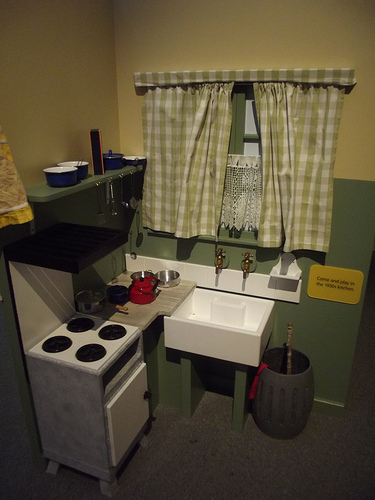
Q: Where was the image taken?
A: It was taken at the kitchen.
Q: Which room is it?
A: It is a kitchen.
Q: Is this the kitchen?
A: Yes, it is the kitchen.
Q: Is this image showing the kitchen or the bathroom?
A: It is showing the kitchen.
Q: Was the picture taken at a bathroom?
A: No, the picture was taken in a kitchen.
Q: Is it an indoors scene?
A: Yes, it is indoors.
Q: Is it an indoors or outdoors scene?
A: It is indoors.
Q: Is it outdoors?
A: No, it is indoors.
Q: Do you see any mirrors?
A: No, there are no mirrors.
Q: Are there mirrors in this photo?
A: No, there are no mirrors.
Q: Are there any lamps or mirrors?
A: No, there are no mirrors or lamps.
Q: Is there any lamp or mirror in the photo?
A: No, there are no mirrors or lamps.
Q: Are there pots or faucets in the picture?
A: Yes, there is a pot.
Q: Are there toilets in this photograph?
A: No, there are no toilets.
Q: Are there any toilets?
A: No, there are no toilets.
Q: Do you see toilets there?
A: No, there are no toilets.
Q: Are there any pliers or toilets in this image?
A: No, there are no toilets or pliers.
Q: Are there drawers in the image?
A: No, there are no drawers.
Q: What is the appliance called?
A: The appliance is a stove.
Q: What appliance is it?
A: The appliance is a stove.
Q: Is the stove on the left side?
A: Yes, the stove is on the left of the image.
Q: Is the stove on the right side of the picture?
A: No, the stove is on the left of the image.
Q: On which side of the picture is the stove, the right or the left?
A: The stove is on the left of the image.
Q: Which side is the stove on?
A: The stove is on the left of the image.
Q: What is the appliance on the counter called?
A: The appliance is a stove.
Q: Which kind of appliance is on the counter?
A: The appliance is a stove.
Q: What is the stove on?
A: The stove is on the counter.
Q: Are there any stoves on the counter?
A: Yes, there is a stove on the counter.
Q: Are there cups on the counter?
A: No, there is a stove on the counter.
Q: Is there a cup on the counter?
A: No, there is a stove on the counter.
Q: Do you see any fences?
A: No, there are no fences.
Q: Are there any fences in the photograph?
A: No, there are no fences.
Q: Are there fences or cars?
A: No, there are no fences or cars.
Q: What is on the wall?
A: The sign is on the wall.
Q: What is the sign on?
A: The sign is on the wall.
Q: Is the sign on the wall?
A: Yes, the sign is on the wall.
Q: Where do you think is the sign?
A: The sign is in the kitchen.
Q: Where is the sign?
A: The sign is in the kitchen.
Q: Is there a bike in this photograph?
A: No, there are no bikes.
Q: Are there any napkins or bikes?
A: No, there are no bikes or napkins.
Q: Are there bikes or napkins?
A: No, there are no bikes or napkins.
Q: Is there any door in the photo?
A: Yes, there is a door.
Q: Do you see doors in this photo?
A: Yes, there is a door.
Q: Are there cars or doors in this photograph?
A: Yes, there is a door.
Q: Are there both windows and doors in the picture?
A: Yes, there are both a door and windows.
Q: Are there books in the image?
A: No, there are no books.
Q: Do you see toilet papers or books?
A: No, there are no books or toilet papers.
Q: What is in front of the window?
A: The sink is in front of the window.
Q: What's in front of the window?
A: The sink is in front of the window.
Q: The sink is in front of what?
A: The sink is in front of the window.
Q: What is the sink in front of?
A: The sink is in front of the window.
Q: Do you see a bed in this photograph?
A: No, there are no beds.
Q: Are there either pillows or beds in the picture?
A: No, there are no beds or pillows.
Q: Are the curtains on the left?
A: No, the curtains are on the right of the image.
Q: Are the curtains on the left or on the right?
A: The curtains are on the right of the image.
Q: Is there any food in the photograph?
A: No, there is no food.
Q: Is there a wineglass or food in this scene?
A: No, there are no food or wine glasses.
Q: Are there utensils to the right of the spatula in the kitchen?
A: Yes, there is a utensil to the right of the spatula.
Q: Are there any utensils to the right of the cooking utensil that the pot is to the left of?
A: Yes, there is a utensil to the right of the spatula.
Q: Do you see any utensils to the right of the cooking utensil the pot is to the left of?
A: Yes, there is a utensil to the right of the spatula.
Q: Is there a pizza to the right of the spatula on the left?
A: No, there is a utensil to the right of the spatula.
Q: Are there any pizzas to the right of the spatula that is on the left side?
A: No, there is a utensil to the right of the spatula.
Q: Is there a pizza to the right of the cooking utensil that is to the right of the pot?
A: No, there is a utensil to the right of the spatula.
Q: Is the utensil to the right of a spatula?
A: Yes, the utensil is to the right of a spatula.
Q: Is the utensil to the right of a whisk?
A: No, the utensil is to the right of a spatula.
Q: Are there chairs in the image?
A: No, there are no chairs.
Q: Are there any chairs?
A: No, there are no chairs.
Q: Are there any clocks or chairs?
A: No, there are no chairs or clocks.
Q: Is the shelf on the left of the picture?
A: Yes, the shelf is on the left of the image.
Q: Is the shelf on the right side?
A: No, the shelf is on the left of the image.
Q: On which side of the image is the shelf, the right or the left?
A: The shelf is on the left of the image.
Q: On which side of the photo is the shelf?
A: The shelf is on the left of the image.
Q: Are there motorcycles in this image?
A: No, there are no motorcycles.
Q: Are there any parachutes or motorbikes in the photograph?
A: No, there are no motorbikes or parachutes.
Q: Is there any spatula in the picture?
A: Yes, there is a spatula.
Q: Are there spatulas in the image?
A: Yes, there is a spatula.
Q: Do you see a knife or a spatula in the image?
A: Yes, there is a spatula.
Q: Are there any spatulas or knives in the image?
A: Yes, there is a spatula.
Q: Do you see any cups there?
A: No, there are no cups.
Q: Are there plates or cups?
A: No, there are no cups or plates.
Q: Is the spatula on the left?
A: Yes, the spatula is on the left of the image.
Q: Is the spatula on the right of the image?
A: No, the spatula is on the left of the image.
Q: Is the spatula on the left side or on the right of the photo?
A: The spatula is on the left of the image.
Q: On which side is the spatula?
A: The spatula is on the left of the image.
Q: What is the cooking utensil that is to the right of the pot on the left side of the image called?
A: The cooking utensil is a spatula.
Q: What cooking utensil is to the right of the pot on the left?
A: The cooking utensil is a spatula.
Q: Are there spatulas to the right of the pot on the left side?
A: Yes, there is a spatula to the right of the pot.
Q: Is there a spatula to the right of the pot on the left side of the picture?
A: Yes, there is a spatula to the right of the pot.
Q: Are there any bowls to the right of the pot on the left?
A: No, there is a spatula to the right of the pot.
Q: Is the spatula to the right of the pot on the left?
A: Yes, the spatula is to the right of the pot.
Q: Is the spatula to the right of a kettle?
A: No, the spatula is to the right of the pot.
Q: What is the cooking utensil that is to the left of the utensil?
A: The cooking utensil is a spatula.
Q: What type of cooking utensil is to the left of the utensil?
A: The cooking utensil is a spatula.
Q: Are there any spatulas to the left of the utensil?
A: Yes, there is a spatula to the left of the utensil.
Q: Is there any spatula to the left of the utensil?
A: Yes, there is a spatula to the left of the utensil.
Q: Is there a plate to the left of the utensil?
A: No, there is a spatula to the left of the utensil.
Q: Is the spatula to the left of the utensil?
A: Yes, the spatula is to the left of the utensil.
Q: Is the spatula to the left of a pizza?
A: No, the spatula is to the left of the utensil.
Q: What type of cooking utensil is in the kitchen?
A: The cooking utensil is a spatula.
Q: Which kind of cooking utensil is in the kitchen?
A: The cooking utensil is a spatula.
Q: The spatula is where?
A: The spatula is in the kitchen.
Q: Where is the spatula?
A: The spatula is in the kitchen.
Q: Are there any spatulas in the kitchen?
A: Yes, there is a spatula in the kitchen.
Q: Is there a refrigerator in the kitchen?
A: No, there is a spatula in the kitchen.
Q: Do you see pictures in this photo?
A: No, there are no pictures.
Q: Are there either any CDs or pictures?
A: No, there are no pictures or cds.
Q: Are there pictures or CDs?
A: No, there are no pictures or cds.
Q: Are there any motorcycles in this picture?
A: No, there are no motorcycles.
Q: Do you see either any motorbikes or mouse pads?
A: No, there are no motorbikes or mouse pads.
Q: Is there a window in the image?
A: Yes, there is a window.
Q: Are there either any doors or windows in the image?
A: Yes, there is a window.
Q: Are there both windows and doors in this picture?
A: Yes, there are both a window and a door.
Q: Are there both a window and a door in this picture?
A: Yes, there are both a window and a door.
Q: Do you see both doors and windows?
A: Yes, there are both a window and a door.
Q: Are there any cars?
A: No, there are no cars.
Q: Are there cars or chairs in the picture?
A: No, there are no cars or chairs.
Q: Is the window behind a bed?
A: No, the window is behind the sink.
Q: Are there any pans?
A: Yes, there is a pan.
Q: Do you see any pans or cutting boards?
A: Yes, there is a pan.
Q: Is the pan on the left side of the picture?
A: Yes, the pan is on the left of the image.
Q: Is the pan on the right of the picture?
A: No, the pan is on the left of the image.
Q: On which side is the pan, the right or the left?
A: The pan is on the left of the image.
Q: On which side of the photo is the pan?
A: The pan is on the left of the image.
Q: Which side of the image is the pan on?
A: The pan is on the left of the image.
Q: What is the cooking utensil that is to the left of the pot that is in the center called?
A: The cooking utensil is a pan.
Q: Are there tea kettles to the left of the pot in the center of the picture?
A: No, there is a pan to the left of the pot.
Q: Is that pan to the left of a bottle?
A: No, the pan is to the left of the pot.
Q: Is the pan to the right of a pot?
A: No, the pan is to the left of a pot.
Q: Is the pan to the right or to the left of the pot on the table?
A: The pan is to the left of the pot.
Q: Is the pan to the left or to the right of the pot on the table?
A: The pan is to the left of the pot.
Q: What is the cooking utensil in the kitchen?
A: The cooking utensil is a pan.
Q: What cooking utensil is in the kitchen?
A: The cooking utensil is a pan.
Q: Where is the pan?
A: The pan is in the kitchen.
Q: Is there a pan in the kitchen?
A: Yes, there is a pan in the kitchen.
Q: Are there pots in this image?
A: Yes, there is a pot.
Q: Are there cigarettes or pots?
A: Yes, there is a pot.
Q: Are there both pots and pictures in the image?
A: No, there is a pot but no pictures.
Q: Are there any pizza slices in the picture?
A: No, there are no pizza slices.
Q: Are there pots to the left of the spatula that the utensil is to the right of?
A: Yes, there is a pot to the left of the spatula.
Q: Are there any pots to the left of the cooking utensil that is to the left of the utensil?
A: Yes, there is a pot to the left of the spatula.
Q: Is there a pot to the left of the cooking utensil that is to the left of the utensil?
A: Yes, there is a pot to the left of the spatula.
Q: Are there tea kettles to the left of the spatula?
A: No, there is a pot to the left of the spatula.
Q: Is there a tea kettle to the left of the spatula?
A: No, there is a pot to the left of the spatula.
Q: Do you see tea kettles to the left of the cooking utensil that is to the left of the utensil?
A: No, there is a pot to the left of the spatula.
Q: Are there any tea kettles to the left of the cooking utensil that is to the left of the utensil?
A: No, there is a pot to the left of the spatula.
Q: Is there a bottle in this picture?
A: No, there are no bottles.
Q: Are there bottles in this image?
A: No, there are no bottles.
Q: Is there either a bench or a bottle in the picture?
A: No, there are no bottles or benches.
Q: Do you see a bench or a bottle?
A: No, there are no bottles or benches.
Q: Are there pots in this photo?
A: Yes, there is a pot.